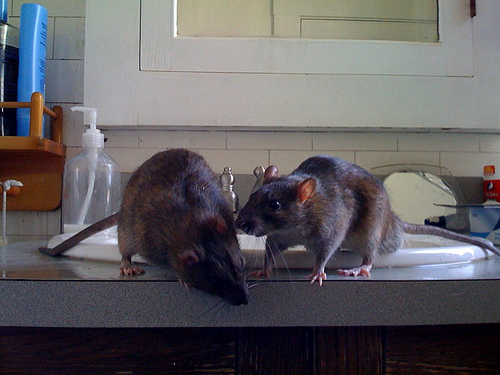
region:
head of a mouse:
[228, 175, 318, 233]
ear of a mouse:
[292, 174, 323, 209]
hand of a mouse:
[251, 240, 284, 280]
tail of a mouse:
[38, 191, 120, 258]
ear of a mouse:
[175, 250, 205, 273]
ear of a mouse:
[196, 215, 236, 243]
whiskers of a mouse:
[240, 239, 298, 289]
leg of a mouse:
[350, 239, 387, 284]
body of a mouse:
[315, 165, 402, 242]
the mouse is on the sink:
[54, 146, 256, 307]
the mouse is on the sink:
[233, 143, 405, 298]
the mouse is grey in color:
[118, 148, 255, 315]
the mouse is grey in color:
[246, 151, 406, 286]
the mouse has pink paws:
[260, 261, 373, 282]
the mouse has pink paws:
[115, 255, 140, 276]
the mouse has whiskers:
[253, 230, 296, 298]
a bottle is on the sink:
[65, 104, 118, 245]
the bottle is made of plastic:
[61, 105, 114, 235]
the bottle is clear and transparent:
[63, 141, 116, 235]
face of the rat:
[236, 166, 299, 246]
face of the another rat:
[184, 245, 264, 327]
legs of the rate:
[295, 237, 373, 297]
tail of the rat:
[43, 209, 113, 269]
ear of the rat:
[293, 174, 334, 210]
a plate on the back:
[383, 156, 477, 233]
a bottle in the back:
[56, 115, 152, 321]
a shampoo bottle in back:
[17, 16, 57, 147]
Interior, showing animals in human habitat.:
[2, 6, 499, 370]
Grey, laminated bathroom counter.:
[10, 241, 73, 320]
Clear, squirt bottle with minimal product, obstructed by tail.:
[67, 103, 123, 250]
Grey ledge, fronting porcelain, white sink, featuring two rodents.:
[62, 155, 475, 306]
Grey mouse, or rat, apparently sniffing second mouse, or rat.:
[235, 150, 417, 287]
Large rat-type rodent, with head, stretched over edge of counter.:
[76, 151, 254, 308]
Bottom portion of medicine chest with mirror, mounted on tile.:
[68, 4, 486, 137]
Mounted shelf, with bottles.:
[3, 13, 71, 215]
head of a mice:
[225, 176, 306, 244]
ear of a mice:
[295, 176, 320, 206]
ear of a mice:
[267, 156, 281, 182]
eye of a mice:
[258, 195, 285, 214]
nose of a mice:
[226, 208, 257, 233]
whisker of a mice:
[245, 234, 295, 277]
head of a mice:
[178, 223, 261, 315]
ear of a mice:
[157, 235, 198, 270]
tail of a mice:
[38, 190, 119, 265]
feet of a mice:
[111, 260, 152, 280]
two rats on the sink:
[67, 120, 429, 301]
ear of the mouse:
[283, 174, 328, 210]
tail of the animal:
[391, 203, 497, 263]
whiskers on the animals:
[243, 220, 309, 283]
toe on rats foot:
[360, 270, 374, 279]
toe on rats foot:
[348, 268, 356, 280]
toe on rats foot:
[340, 268, 350, 280]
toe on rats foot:
[318, 273, 325, 285]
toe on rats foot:
[321, 270, 329, 281]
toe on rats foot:
[308, 273, 314, 285]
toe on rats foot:
[261, 267, 273, 279]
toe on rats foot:
[119, 263, 134, 278]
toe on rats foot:
[130, 263, 142, 273]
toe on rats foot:
[117, 265, 124, 277]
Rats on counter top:
[81, 149, 421, 297]